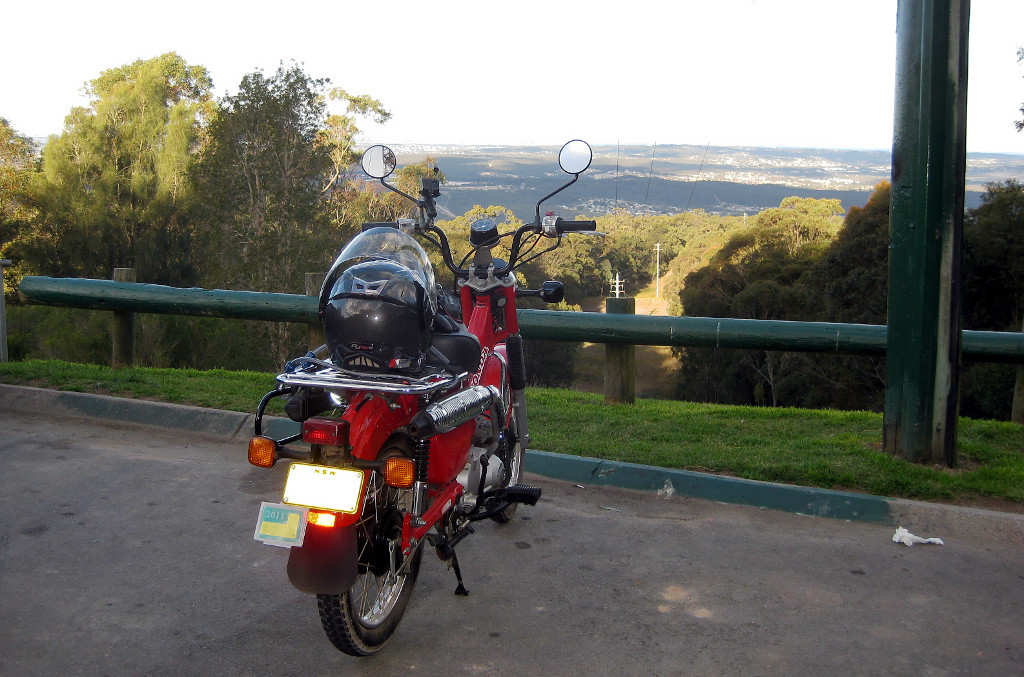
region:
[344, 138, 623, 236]
2 mirrors connected to handlebars.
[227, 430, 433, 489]
Orange lights on back of bike.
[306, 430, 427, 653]
Back tire is black in color.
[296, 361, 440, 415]
Silver rack on back of bike.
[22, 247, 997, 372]
Green railing in front of bike.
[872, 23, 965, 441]
Large green pole near railing.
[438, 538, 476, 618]
Black kickstand on bike.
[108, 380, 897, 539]
Green curb near grass.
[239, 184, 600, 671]
moped is red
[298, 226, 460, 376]
helmet is black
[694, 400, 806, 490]
grass is short and green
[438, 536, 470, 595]
kick stand is touching pavement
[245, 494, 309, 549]
yellow and blue license plate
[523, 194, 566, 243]
metal bracket on handlebar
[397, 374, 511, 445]
muffler is shiny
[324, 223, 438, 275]
clear face shield on black helmet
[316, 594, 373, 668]
tires on moped are worn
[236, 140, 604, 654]
A red mortor bike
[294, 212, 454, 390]
Black motorbike helmet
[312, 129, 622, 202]
rear view mirrors on a motorbike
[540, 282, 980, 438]
Metal and wood post railings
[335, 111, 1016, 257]
View of the valley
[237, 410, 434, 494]
Orange and red tail lights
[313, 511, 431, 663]
Back tire of a motor bike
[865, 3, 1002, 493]
Green painted wooden pole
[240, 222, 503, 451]
Black helmet on motor bike rack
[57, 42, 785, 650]
The red motorcycle is parked on the curb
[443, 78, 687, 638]
The motorcycle has a mirror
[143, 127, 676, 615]
The black helmet is on the back of the motorcycle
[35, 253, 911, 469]
The fence is a green bar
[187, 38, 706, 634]
The red motorcycle has a black kickstand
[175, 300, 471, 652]
The motorcycle has a blue tag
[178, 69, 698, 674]
The motorcycle has a red tail light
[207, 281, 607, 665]
The motorcycle has a license plate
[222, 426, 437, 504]
tail lights on the bike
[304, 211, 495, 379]
a black bike helmet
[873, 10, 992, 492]
a dark green pole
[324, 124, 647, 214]
2 round rearview mirrors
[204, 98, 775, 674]
the bike is red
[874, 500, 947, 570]
paper on the ground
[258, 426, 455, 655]
back tire on the bike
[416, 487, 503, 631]
kick stand on bike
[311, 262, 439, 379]
a black motorcycle helmet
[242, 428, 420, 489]
rear lights on a bike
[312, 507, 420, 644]
rear tire on a bike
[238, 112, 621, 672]
a small red motorcycle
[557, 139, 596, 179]
a rear view mirror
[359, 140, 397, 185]
a round bike mirror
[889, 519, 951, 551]
debris on the road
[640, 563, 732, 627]
sunlight on the road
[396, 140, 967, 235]
a low country valley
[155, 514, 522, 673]
back of a tire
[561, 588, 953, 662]
a dirty ground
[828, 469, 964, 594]
a piece of crumbled paper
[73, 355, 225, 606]
grass and asphlat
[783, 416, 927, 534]
a wooden beam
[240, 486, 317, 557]
part of a motorcycle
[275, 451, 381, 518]
part of a motorcycle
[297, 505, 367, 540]
part of a motorcycle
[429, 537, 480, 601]
part of a motorcycle